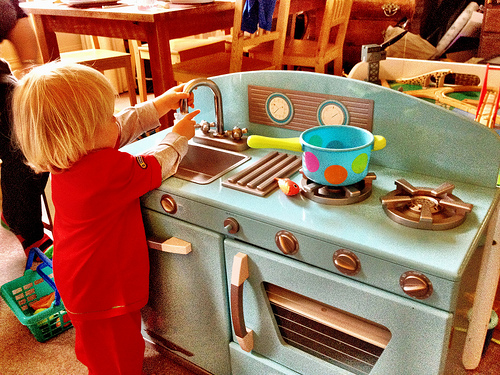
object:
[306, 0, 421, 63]
bureau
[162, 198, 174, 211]
knob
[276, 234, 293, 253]
knob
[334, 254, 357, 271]
knob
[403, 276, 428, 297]
knob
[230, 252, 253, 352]
handle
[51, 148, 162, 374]
red clothes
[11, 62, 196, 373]
boy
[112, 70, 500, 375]
kitchen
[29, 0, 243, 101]
table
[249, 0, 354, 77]
chairs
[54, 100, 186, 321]
casual shirt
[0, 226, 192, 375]
carpet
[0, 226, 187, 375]
floor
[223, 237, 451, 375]
door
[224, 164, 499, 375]
stove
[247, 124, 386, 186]
toy pot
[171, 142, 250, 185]
sink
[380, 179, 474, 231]
burner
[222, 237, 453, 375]
oven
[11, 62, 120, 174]
head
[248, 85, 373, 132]
decoration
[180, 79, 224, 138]
faucet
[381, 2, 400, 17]
handles